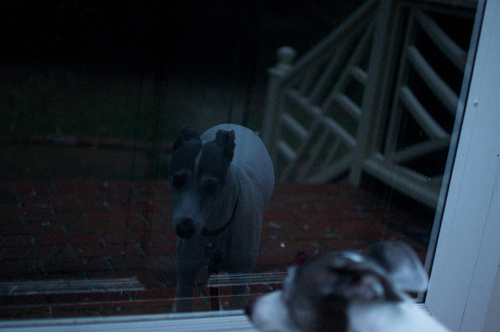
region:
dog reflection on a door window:
[138, 99, 398, 329]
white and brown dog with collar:
[162, 119, 302, 310]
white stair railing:
[252, 9, 472, 286]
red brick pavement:
[34, 174, 146, 261]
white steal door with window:
[424, 22, 497, 314]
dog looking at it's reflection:
[157, 117, 411, 329]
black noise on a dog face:
[170, 169, 216, 246]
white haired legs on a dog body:
[168, 239, 295, 319]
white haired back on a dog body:
[192, 109, 293, 207]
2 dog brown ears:
[296, 223, 457, 321]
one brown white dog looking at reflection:
[124, 111, 290, 326]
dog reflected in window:
[143, 101, 256, 266]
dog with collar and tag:
[147, 70, 272, 284]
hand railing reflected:
[220, 27, 455, 267]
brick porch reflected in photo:
[11, 139, 336, 328]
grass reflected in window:
[16, 71, 376, 208]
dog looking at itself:
[233, 239, 465, 328]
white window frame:
[157, 40, 474, 330]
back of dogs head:
[248, 254, 430, 330]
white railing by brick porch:
[214, 74, 421, 236]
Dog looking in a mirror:
[150, 105, 434, 325]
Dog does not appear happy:
[159, 119, 240, 239]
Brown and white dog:
[158, 109, 282, 306]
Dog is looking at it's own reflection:
[223, 239, 434, 330]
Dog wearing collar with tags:
[181, 214, 249, 280]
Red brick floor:
[3, 165, 177, 320]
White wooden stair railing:
[263, 5, 476, 213]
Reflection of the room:
[3, 2, 480, 319]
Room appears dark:
[5, 2, 492, 198]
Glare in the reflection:
[8, 262, 282, 304]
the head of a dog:
[159, 119, 246, 241]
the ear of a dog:
[208, 124, 248, 158]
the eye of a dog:
[200, 173, 229, 197]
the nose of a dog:
[170, 212, 197, 241]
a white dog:
[234, 225, 460, 330]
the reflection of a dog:
[158, 112, 298, 314]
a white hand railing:
[254, 1, 394, 186]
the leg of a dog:
[165, 265, 207, 312]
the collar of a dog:
[193, 173, 245, 238]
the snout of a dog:
[166, 190, 216, 244]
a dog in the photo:
[156, 103, 318, 275]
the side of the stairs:
[259, 28, 431, 157]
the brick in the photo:
[38, 177, 108, 272]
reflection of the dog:
[141, 94, 446, 321]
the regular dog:
[228, 230, 468, 325]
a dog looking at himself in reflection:
[131, 116, 383, 330]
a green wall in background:
[47, 57, 204, 133]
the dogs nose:
[172, 207, 222, 259]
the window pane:
[111, 317, 233, 329]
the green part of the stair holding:
[278, 21, 483, 224]